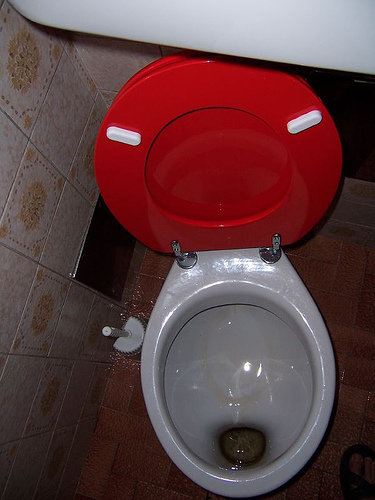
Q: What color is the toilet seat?
A: Red.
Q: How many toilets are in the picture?
A: One.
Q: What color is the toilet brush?
A: White.